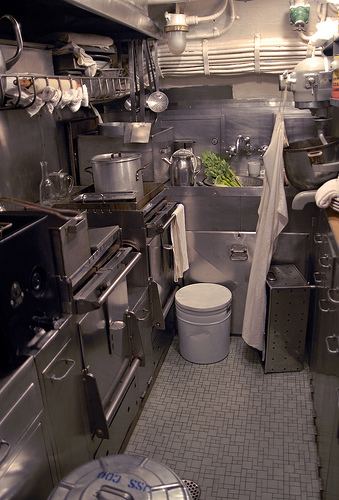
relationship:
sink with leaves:
[188, 114, 260, 195] [198, 149, 239, 186]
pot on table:
[84, 152, 151, 205] [146, 182, 158, 194]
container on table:
[38, 160, 57, 207] [94, 227, 109, 239]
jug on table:
[165, 151, 198, 186] [165, 183, 184, 190]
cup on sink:
[247, 159, 261, 179] [196, 167, 263, 198]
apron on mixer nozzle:
[238, 107, 292, 358] [274, 69, 291, 93]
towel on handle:
[170, 212, 193, 284] [154, 216, 173, 233]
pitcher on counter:
[52, 173, 75, 198] [74, 182, 85, 196]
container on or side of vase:
[38, 160, 57, 207] [56, 170, 72, 201]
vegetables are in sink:
[202, 152, 235, 189] [214, 160, 255, 198]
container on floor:
[172, 281, 234, 367] [196, 377, 284, 464]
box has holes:
[269, 271, 302, 374] [269, 340, 277, 352]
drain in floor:
[181, 479, 198, 498] [187, 388, 264, 469]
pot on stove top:
[93, 152, 144, 206] [129, 187, 175, 208]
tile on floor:
[203, 457, 211, 465] [191, 412, 242, 445]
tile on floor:
[184, 449, 193, 457] [215, 419, 274, 450]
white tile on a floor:
[267, 449, 278, 458] [156, 382, 299, 483]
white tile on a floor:
[245, 463, 251, 468] [166, 369, 299, 472]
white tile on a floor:
[289, 483, 300, 495] [164, 382, 302, 480]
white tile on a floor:
[288, 453, 299, 462] [173, 385, 301, 471]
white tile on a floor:
[250, 421, 262, 432] [169, 380, 308, 466]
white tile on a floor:
[244, 464, 255, 470] [155, 382, 301, 464]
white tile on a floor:
[236, 488, 247, 496] [159, 375, 311, 463]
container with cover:
[172, 281, 234, 367] [173, 281, 234, 312]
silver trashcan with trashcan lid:
[45, 453, 187, 499] [41, 453, 189, 500]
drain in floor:
[181, 479, 199, 498] [149, 378, 303, 471]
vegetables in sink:
[202, 152, 235, 189] [197, 172, 264, 186]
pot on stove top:
[84, 152, 151, 205] [75, 183, 173, 209]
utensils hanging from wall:
[145, 31, 168, 116] [251, 8, 287, 30]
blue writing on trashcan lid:
[95, 469, 155, 496] [41, 453, 190, 497]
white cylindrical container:
[195, 293, 217, 302] [178, 281, 234, 367]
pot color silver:
[84, 152, 151, 205] [110, 165, 132, 179]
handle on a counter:
[49, 356, 74, 384] [33, 316, 96, 476]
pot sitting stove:
[84, 152, 151, 205] [93, 179, 191, 332]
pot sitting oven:
[84, 152, 151, 205] [83, 184, 205, 330]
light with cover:
[288, 18, 327, 56] [285, 7, 326, 39]